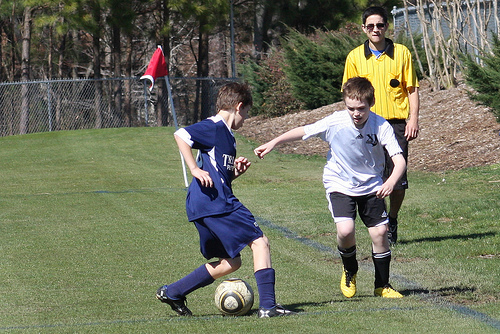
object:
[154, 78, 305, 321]
person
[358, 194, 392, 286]
leg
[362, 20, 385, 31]
sunglasses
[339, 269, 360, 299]
feet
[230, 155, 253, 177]
hand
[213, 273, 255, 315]
soccer ball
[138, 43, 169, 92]
flag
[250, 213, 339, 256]
blue line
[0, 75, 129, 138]
fence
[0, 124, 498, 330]
field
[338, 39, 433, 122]
t-shirt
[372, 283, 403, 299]
soccer boots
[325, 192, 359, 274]
leg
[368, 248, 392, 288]
black sock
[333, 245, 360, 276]
black sock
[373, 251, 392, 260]
white stripe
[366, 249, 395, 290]
sock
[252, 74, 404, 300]
boy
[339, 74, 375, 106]
hair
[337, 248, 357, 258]
stripe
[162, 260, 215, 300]
sock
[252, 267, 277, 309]
sock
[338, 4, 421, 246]
man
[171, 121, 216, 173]
arm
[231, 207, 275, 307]
leg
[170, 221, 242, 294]
leg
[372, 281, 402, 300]
foot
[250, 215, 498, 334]
line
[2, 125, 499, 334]
grass